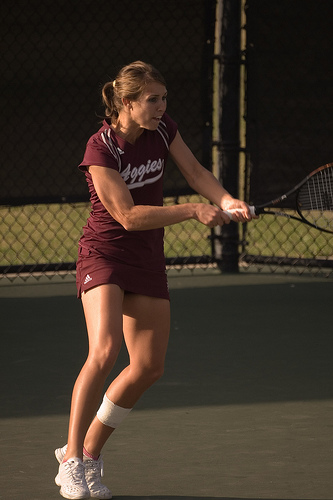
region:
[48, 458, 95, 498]
white shoes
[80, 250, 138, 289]
red shorts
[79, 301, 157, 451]
legs of tennis player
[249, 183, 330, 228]
A tennis racket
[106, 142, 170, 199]
Jersey of tennis player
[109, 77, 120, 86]
Hair tie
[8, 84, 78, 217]
A metal gate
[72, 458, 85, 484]
shoe laces on shoes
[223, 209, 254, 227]
white handle on tennis racket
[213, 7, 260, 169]
Metal poles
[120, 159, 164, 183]
the words on the woman's top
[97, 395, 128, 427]
the white bandage on the woman's calf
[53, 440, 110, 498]
the woman's white shoes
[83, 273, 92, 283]
the logo on the woman's skirt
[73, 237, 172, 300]
the woman's tennis skirt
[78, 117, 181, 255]
the woman's maroon top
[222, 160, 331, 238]
the tennis racquet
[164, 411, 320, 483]
the ground of the tennis court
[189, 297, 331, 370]
the shadow on the tennis court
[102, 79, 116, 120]
the ponytail on the woman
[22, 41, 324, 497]
woman palying tennis on a court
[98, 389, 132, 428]
ace bandage on woman's calf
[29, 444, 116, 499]
white tennis sneakers on woman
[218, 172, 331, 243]
black racket in woman's hands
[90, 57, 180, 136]
face of a female tennis player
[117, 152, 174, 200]
logo on woman's shirt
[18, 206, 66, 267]
fence of a tennis court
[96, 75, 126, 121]
ponytail in woman's hair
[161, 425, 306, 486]
ground of a tennis court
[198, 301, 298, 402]
shadow casted on the ground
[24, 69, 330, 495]
a woman playing tennis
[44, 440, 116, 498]
woman wearing white sneakers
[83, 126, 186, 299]
woman wearing a red uniform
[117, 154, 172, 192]
a white logo on a uniform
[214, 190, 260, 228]
white handle of a tennis racket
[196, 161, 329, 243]
woman holding a tennis racket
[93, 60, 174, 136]
woman with a pony tail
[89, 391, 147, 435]
a white bandage around the leg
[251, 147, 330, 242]
a black tennis racket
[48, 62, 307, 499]
a tennis player about to hit a ball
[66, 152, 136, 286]
a woman playing tennis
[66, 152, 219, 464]
a woman playing tennis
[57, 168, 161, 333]
a woman playing tennis